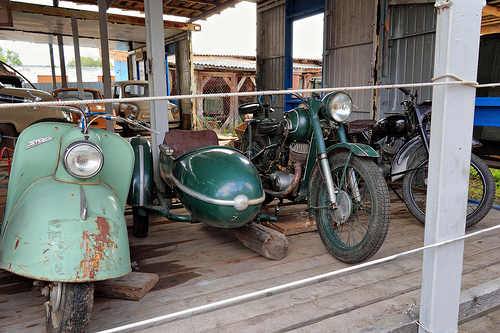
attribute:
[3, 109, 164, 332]
moped — old, in garage, in need of repair, antique, mint green, green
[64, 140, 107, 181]
headlight — surrounded by chrome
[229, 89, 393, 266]
moped — old, in garage, in need of repair, antique, green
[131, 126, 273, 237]
sidecar — dark green, green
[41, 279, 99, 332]
wheel — part , front wheel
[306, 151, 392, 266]
wheel — front wheel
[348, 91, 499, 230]
moped — old, in garage, in need of repair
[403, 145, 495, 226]
wheel — front wheel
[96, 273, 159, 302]
piece of wood — piece 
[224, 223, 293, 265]
piece of wood — a small log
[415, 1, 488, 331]
post — metal, thin, white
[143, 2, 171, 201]
post — metal, thin, white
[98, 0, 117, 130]
post — metal, thin, white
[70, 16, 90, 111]
post — metal, thin, white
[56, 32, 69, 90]
post — metal, thin, white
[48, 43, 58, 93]
post — metal, thin, white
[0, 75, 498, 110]
wire — metal, thin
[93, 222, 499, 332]
wire — metal, thin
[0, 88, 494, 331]
cycle collection — antique, old, parked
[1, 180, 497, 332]
floor — part 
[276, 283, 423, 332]
line — part 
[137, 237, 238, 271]
line — part 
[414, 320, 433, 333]
rope — part 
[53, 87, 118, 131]
car — in background, orange, old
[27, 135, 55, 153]
nameplate — chrome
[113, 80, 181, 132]
car — in background, old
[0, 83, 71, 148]
car — in background, old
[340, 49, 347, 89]
beam — white, wooden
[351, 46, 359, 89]
beam — white, wooden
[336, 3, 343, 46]
beam — white, wooden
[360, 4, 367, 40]
beam — white, wooden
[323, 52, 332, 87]
beam — white, wooden